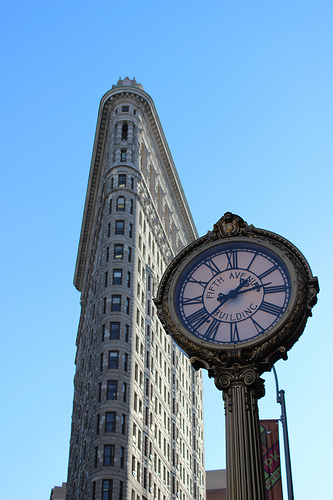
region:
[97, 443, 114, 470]
Window of a building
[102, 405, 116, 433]
Window of a building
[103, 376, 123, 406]
Window of a building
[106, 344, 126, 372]
Window of a building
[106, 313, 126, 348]
Window of a building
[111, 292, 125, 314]
Window of a building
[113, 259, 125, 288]
Window of a building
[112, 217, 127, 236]
Window of a building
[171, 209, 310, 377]
Clock on a pole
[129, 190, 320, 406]
"Fifth Avenue Building"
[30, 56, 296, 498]
A tower in the shot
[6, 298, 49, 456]
This is the sky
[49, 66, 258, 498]
This building is tall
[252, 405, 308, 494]
A sign on a pole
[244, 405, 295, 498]
The flag has words on it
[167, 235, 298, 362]
The face of a clock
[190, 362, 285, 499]
Pole is brown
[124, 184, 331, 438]
Clock on the street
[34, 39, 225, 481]
Flat iron building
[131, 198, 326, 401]
Clock along fifth ave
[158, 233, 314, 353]
clock on the tower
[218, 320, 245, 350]
number on the clock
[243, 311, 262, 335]
number on the clock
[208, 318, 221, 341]
number on the clock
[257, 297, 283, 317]
number on the clock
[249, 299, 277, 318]
number on the clock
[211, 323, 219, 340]
number on the clock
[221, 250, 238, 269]
number on the clock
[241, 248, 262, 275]
number on the clock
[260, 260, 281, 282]
number on the clock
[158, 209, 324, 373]
A clock on a pole outside of a building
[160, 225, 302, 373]
fifth ave building clock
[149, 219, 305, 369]
fifth ave building clock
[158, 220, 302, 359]
fifth ave building clock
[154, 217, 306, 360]
fifth ave building clock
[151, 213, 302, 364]
fifth ave building clock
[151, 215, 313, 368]
fifth ave building clock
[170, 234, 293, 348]
black and white elevated clock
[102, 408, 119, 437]
window on side of building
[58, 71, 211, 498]
tall narrow building